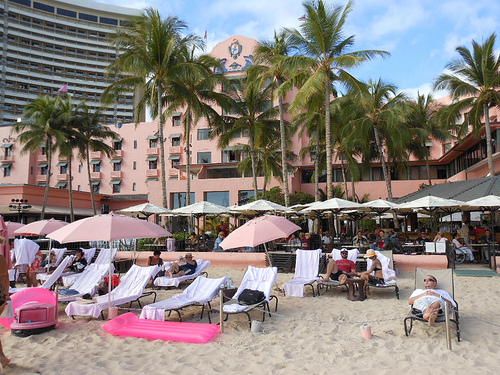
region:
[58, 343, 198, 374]
sand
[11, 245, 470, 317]
lounge chairs on the sand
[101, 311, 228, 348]
pink inflatable object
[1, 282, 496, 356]
small posts with a chain forming a barrier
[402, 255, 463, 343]
man reclining in lounge chair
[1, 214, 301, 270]
large pink umbrellas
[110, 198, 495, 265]
large white umbrellas over tables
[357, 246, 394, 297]
woman sitting on the side of a lounge chair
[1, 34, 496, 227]
large pink building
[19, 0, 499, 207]
palm trees partially obscuring building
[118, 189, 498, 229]
Umbrellas in a row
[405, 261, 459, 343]
Man laying on chair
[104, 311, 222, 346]
Pink floatie on ground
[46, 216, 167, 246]
Large pink umbrella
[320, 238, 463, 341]
People on sandy beach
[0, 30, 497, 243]
Building is pink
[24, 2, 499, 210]
Palm trees in front of building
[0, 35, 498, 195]
Building behind palm trees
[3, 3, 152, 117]
Tall building in distance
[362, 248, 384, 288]
Woman in yellow hat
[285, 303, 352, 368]
Sand on a beach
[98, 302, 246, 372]
Pink mattress on a beach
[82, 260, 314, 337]
Beach towels with chairs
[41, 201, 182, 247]
Umbrella on the beach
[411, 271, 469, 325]
Man laying on a chair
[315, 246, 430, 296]
People on the beach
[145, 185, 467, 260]
White umbrellas on a patio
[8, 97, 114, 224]
Palm trees by a beach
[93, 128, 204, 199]
Windows on a building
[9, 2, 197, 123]
Tall building by a beach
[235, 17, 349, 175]
tall trees are visible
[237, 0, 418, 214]
tall trees are visible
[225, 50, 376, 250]
tall trees are visible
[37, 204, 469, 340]
people relaxing on beach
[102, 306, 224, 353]
pink inflatable raft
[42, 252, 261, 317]
large white towels cover the chairs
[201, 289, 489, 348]
small chain to serve as boundary for hotel guests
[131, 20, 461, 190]
palm trees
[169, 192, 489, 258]
people at tables with umbrellas looking toward the beach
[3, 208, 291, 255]
pink beach umbrellas are open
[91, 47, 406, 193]
resort is pink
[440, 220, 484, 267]
person in wheelchair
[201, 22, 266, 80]
blue decoration on pink building